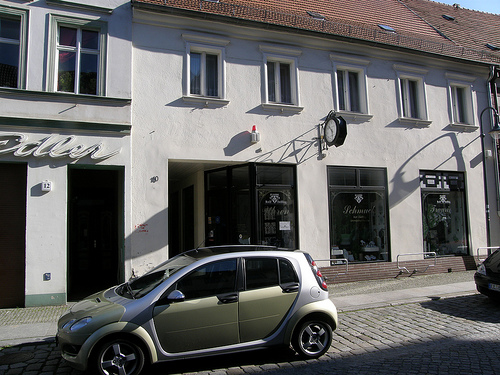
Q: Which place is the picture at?
A: It is at the street.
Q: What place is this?
A: It is a street.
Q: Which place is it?
A: It is a street.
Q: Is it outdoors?
A: Yes, it is outdoors.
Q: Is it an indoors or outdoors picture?
A: It is outdoors.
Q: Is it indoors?
A: No, it is outdoors.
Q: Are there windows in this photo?
A: Yes, there is a window.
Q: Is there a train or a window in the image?
A: Yes, there is a window.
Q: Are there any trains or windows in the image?
A: Yes, there is a window.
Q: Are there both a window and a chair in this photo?
A: No, there is a window but no chairs.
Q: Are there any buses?
A: No, there are no buses.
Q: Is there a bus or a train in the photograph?
A: No, there are no buses or trains.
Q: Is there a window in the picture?
A: Yes, there is a window.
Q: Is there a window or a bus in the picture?
A: Yes, there is a window.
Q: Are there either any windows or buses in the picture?
A: Yes, there is a window.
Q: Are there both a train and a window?
A: No, there is a window but no trains.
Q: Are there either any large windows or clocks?
A: Yes, there is a large window.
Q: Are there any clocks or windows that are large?
A: Yes, the window is large.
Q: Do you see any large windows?
A: Yes, there is a large window.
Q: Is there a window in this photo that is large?
A: Yes, there is a window that is large.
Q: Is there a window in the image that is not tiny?
A: Yes, there is a large window.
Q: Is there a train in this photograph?
A: No, there are no trains.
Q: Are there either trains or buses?
A: No, there are no trains or buses.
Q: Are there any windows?
A: Yes, there is a window.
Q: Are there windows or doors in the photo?
A: Yes, there is a window.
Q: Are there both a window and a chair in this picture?
A: No, there is a window but no chairs.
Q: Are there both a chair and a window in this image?
A: No, there is a window but no chairs.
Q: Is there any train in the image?
A: No, there are no trains.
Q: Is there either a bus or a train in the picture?
A: No, there are no trains or buses.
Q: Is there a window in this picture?
A: Yes, there is a window.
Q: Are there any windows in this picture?
A: Yes, there is a window.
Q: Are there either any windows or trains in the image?
A: Yes, there is a window.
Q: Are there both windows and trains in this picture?
A: No, there is a window but no trains.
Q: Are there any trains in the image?
A: No, there are no trains.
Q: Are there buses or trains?
A: No, there are no trains or buses.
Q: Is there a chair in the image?
A: No, there are no chairs.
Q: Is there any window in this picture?
A: Yes, there is a window.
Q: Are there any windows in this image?
A: Yes, there is a window.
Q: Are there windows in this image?
A: Yes, there is a window.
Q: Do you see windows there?
A: Yes, there is a window.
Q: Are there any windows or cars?
A: Yes, there is a window.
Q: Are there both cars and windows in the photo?
A: Yes, there are both a window and a car.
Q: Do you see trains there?
A: No, there are no trains.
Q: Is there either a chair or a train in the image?
A: No, there are no trains or chairs.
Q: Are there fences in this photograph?
A: No, there are no fences.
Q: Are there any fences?
A: No, there are no fences.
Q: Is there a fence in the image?
A: No, there are no fences.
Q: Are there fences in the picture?
A: No, there are no fences.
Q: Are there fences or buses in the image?
A: No, there are no fences or buses.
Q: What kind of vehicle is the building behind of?
A: The building is behind the car.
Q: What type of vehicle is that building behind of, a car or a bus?
A: The building is behind a car.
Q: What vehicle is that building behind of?
A: The building is behind the car.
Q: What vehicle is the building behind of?
A: The building is behind the car.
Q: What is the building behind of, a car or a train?
A: The building is behind a car.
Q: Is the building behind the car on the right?
A: Yes, the building is behind the car.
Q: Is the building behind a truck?
A: No, the building is behind the car.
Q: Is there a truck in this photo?
A: No, there are no trucks.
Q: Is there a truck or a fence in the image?
A: No, there are no trucks or fences.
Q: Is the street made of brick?
A: Yes, the street is made of brick.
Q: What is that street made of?
A: The street is made of brick.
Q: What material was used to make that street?
A: The street is made of brick.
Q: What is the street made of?
A: The street is made of brick.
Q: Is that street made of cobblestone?
A: No, the street is made of brick.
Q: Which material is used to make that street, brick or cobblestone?
A: The street is made of brick.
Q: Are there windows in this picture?
A: Yes, there is a window.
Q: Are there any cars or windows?
A: Yes, there is a window.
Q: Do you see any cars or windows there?
A: Yes, there is a window.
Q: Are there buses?
A: No, there are no buses.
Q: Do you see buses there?
A: No, there are no buses.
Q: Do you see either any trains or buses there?
A: No, there are no buses or trains.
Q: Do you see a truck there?
A: No, there are no trucks.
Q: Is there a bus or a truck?
A: No, there are no trucks or buses.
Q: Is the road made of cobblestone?
A: Yes, the road is made of cobblestone.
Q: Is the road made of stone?
A: No, the road is made of cobblestone.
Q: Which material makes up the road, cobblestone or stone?
A: The road is made of cobblestone.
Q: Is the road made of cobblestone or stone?
A: The road is made of cobblestone.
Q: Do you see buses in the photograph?
A: No, there are no buses.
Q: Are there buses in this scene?
A: No, there are no buses.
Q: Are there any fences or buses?
A: No, there are no buses or fences.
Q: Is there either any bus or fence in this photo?
A: No, there are no buses or fences.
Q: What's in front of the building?
A: The car is in front of the building.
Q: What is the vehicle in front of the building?
A: The vehicle is a car.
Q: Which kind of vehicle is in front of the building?
A: The vehicle is a car.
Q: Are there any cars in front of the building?
A: Yes, there is a car in front of the building.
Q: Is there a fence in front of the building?
A: No, there is a car in front of the building.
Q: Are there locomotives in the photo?
A: No, there are no locomotives.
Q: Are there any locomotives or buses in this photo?
A: No, there are no locomotives or buses.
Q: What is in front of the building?
A: The car is in front of the building.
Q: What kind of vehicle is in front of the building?
A: The vehicle is a car.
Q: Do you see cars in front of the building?
A: Yes, there is a car in front of the building.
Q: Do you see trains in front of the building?
A: No, there is a car in front of the building.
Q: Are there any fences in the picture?
A: No, there are no fences.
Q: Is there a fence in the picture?
A: No, there are no fences.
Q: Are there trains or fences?
A: No, there are no fences or trains.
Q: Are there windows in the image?
A: Yes, there is a window.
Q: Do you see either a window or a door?
A: Yes, there is a window.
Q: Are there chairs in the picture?
A: No, there are no chairs.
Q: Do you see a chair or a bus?
A: No, there are no chairs or buses.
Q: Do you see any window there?
A: Yes, there is a window.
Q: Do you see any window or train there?
A: Yes, there is a window.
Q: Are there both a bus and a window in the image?
A: No, there is a window but no buses.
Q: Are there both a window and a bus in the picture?
A: No, there is a window but no buses.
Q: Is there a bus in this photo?
A: No, there are no buses.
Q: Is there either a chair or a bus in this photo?
A: No, there are no buses or chairs.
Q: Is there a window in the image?
A: Yes, there is a window.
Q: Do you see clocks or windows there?
A: Yes, there is a window.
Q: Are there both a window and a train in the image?
A: No, there is a window but no trains.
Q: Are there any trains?
A: No, there are no trains.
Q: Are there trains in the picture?
A: No, there are no trains.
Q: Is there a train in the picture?
A: No, there are no trains.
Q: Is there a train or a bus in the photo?
A: No, there are no trains or buses.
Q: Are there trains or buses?
A: No, there are no trains or buses.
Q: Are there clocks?
A: Yes, there is a clock.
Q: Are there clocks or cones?
A: Yes, there is a clock.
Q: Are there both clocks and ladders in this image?
A: No, there is a clock but no ladders.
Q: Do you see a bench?
A: No, there are no benches.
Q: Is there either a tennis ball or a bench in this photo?
A: No, there are no benches or tennis balls.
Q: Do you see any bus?
A: No, there are no buses.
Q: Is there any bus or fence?
A: No, there are no buses or fences.